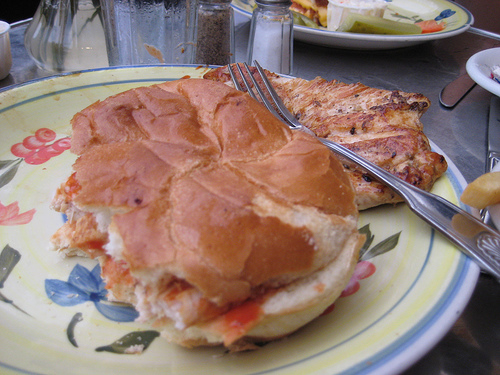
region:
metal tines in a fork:
[229, 68, 256, 85]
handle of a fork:
[407, 186, 477, 241]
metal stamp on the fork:
[476, 231, 498, 253]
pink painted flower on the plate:
[16, 127, 59, 164]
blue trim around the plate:
[407, 310, 439, 342]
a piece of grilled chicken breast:
[341, 88, 401, 140]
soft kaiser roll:
[141, 110, 221, 208]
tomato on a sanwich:
[219, 308, 248, 330]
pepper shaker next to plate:
[193, 8, 238, 56]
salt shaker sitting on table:
[259, 0, 306, 68]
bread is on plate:
[75, 85, 354, 332]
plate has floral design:
[2, 196, 144, 353]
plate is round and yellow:
[8, 69, 479, 373]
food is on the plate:
[77, 79, 343, 323]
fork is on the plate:
[230, 55, 499, 275]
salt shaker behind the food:
[250, 3, 297, 77]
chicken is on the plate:
[210, 61, 446, 206]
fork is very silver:
[230, 60, 499, 260]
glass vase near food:
[32, 6, 121, 67]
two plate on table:
[5, 4, 482, 373]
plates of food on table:
[15, 2, 490, 357]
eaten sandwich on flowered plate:
[55, 90, 377, 345]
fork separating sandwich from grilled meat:
[226, 50, 493, 305]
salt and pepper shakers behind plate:
[180, 0, 291, 85]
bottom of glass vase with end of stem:
[21, 0, 106, 75]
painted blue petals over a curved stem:
[36, 236, 136, 352]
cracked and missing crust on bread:
[75, 75, 370, 300]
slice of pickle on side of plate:
[271, 2, 472, 39]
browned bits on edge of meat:
[377, 85, 457, 170]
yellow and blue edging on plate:
[376, 263, 464, 359]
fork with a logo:
[225, 57, 498, 272]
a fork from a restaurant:
[223, 56, 498, 286]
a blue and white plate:
[4, 58, 484, 374]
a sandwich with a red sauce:
[49, 73, 351, 353]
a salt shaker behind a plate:
[244, 0, 298, 77]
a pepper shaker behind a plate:
[194, 0, 236, 67]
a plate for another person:
[224, 0, 484, 47]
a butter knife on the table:
[482, 90, 498, 236]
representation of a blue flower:
[40, 263, 142, 324]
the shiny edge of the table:
[468, 3, 498, 53]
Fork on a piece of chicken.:
[217, 55, 297, 131]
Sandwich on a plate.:
[61, 81, 340, 331]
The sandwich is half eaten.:
[60, 130, 190, 340]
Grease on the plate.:
[23, 72, 130, 108]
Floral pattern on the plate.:
[4, 185, 98, 317]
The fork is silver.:
[350, 146, 497, 239]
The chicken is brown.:
[344, 106, 400, 147]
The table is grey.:
[379, 53, 434, 83]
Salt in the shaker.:
[253, 10, 298, 63]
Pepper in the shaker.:
[198, 6, 238, 66]